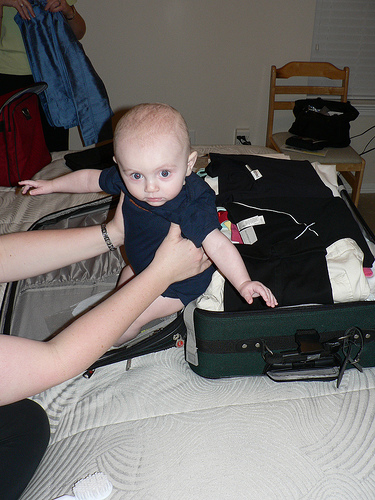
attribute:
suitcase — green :
[193, 124, 288, 263]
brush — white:
[52, 471, 115, 498]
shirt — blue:
[98, 164, 221, 305]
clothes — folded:
[198, 151, 374, 311]